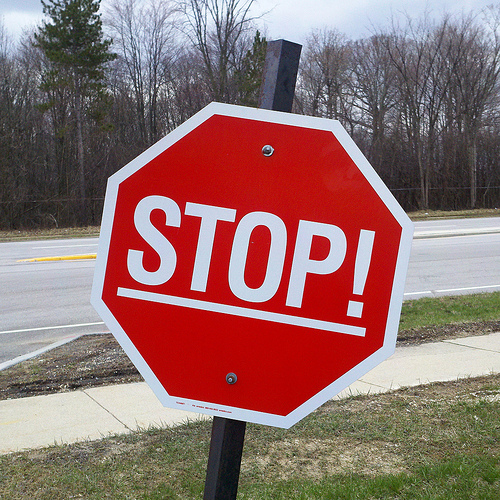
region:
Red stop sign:
[102, 90, 406, 430]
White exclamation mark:
[346, 210, 381, 327]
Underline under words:
[112, 277, 371, 357]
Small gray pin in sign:
[217, 362, 245, 394]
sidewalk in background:
[15, 322, 498, 452]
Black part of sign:
[208, 412, 241, 498]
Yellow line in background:
[18, 249, 103, 264]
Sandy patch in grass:
[285, 432, 402, 476]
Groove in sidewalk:
[81, 385, 133, 440]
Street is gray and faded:
[417, 220, 499, 292]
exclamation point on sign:
[340, 226, 375, 331]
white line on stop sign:
[117, 305, 359, 338]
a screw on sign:
[207, 360, 253, 395]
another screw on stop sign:
[247, 141, 297, 177]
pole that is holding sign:
[207, 413, 254, 498]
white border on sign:
[120, 312, 133, 361]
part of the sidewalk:
[24, 385, 129, 429]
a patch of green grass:
[410, 460, 472, 490]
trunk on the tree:
[467, 154, 482, 208]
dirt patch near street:
[49, 344, 105, 377]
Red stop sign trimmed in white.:
[92, 99, 416, 435]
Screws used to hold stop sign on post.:
[217, 138, 275, 387]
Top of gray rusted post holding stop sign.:
[246, 33, 312, 115]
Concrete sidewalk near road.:
[6, 375, 160, 461]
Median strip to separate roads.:
[416, 224, 498, 243]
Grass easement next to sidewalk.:
[407, 288, 499, 343]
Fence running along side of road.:
[403, 176, 498, 215]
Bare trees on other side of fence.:
[358, 10, 498, 212]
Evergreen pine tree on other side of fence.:
[35, 3, 120, 215]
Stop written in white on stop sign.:
[124, 187, 379, 349]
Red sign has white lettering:
[126, 196, 380, 328]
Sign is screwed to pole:
[192, 365, 262, 493]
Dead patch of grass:
[254, 441, 386, 483]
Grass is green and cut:
[247, 475, 499, 497]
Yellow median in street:
[18, 248, 94, 267]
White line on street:
[1, 325, 74, 338]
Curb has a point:
[63, 326, 102, 341]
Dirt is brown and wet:
[13, 368, 95, 390]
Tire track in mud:
[15, 360, 108, 390]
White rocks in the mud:
[70, 347, 122, 377]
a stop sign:
[133, 156, 362, 470]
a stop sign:
[161, 263, 335, 495]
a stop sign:
[130, 207, 274, 409]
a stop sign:
[229, 209, 350, 413]